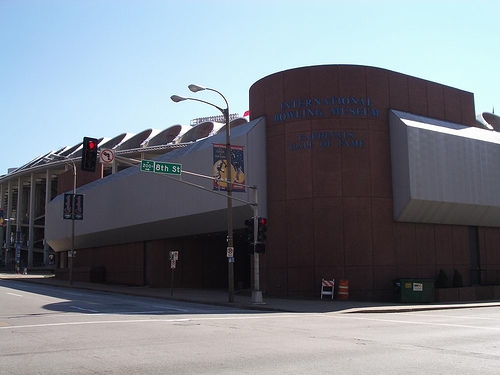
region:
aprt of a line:
[313, 177, 366, 260]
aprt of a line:
[336, 223, 347, 255]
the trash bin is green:
[406, 287, 424, 297]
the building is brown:
[330, 191, 365, 228]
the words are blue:
[299, 130, 342, 147]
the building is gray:
[418, 150, 449, 175]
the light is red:
[258, 215, 268, 225]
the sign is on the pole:
[157, 163, 182, 177]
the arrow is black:
[103, 150, 110, 162]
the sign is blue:
[14, 240, 21, 252]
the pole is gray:
[250, 263, 262, 281]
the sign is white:
[226, 247, 232, 257]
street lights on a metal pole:
[167, 79, 248, 313]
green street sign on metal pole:
[135, 156, 186, 179]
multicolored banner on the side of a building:
[208, 138, 252, 204]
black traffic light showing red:
[77, 133, 100, 177]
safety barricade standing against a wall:
[318, 274, 338, 302]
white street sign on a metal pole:
[97, 145, 116, 167]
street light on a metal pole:
[41, 147, 79, 292]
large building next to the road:
[2, 62, 497, 308]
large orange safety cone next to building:
[335, 276, 352, 303]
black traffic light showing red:
[253, 211, 268, 246]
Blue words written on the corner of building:
[267, 91, 378, 155]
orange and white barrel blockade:
[335, 278, 351, 305]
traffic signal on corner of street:
[240, 214, 270, 306]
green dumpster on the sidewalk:
[393, 273, 432, 308]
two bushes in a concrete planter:
[433, 265, 470, 300]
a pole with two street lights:
[165, 83, 230, 128]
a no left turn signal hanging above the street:
[100, 147, 119, 169]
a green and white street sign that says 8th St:
[153, 160, 183, 175]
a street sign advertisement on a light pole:
[207, 140, 248, 195]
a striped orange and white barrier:
[317, 275, 336, 300]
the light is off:
[188, 83, 202, 93]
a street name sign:
[140, 158, 179, 173]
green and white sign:
[141, 160, 179, 175]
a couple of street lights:
[170, 83, 236, 304]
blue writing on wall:
[272, 100, 381, 150]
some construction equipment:
[320, 278, 347, 299]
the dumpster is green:
[398, 276, 436, 299]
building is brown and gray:
[57, 63, 498, 301]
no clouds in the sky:
[2, 2, 499, 179]